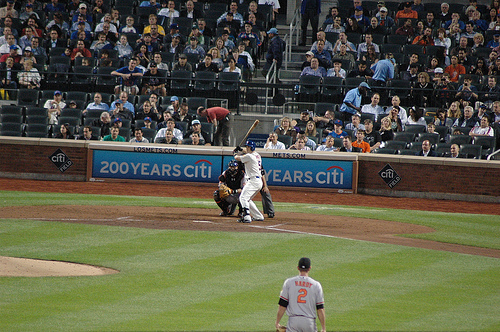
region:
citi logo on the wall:
[48, 147, 73, 169]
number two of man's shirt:
[290, 275, 317, 310]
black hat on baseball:
[297, 253, 315, 270]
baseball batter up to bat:
[240, 105, 266, 222]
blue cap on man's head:
[50, 85, 67, 97]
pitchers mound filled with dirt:
[2, 253, 129, 293]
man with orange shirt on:
[352, 127, 373, 149]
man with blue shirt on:
[342, 74, 378, 114]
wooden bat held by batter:
[217, 113, 258, 163]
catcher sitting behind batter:
[213, 153, 253, 211]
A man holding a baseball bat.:
[214, 114, 286, 231]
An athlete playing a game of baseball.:
[195, 103, 296, 247]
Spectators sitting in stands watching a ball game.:
[8, 4, 495, 142]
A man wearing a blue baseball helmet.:
[206, 118, 296, 239]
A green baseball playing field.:
[6, 185, 250, 329]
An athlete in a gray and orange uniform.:
[245, 240, 354, 329]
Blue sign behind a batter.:
[78, 140, 224, 186]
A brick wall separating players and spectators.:
[366, 157, 497, 206]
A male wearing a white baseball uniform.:
[212, 111, 286, 235]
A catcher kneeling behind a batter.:
[201, 146, 295, 240]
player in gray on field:
[259, 225, 339, 325]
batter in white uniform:
[217, 137, 268, 231]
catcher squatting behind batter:
[209, 141, 254, 227]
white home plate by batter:
[192, 212, 217, 230]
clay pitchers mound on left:
[7, 247, 120, 279]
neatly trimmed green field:
[144, 238, 373, 313]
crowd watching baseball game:
[43, 4, 499, 149]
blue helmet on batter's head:
[244, 134, 263, 156]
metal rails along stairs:
[259, 61, 291, 93]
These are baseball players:
[191, 127, 289, 326]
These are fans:
[91, 5, 312, 147]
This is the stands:
[186, 47, 261, 101]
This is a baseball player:
[221, 228, 366, 329]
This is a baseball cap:
[265, 235, 317, 276]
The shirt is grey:
[268, 260, 337, 324]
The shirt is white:
[218, 125, 275, 203]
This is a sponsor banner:
[106, 118, 260, 209]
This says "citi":
[381, 152, 416, 246]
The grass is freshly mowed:
[154, 303, 166, 315]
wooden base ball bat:
[231, 113, 262, 153]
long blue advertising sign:
[87, 140, 382, 195]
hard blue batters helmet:
[242, 136, 259, 153]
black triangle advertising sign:
[47, 145, 85, 170]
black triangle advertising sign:
[376, 158, 406, 190]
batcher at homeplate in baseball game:
[212, 157, 254, 209]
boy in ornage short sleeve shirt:
[353, 125, 370, 151]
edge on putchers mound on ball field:
[2, 239, 139, 317]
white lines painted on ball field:
[106, 196, 393, 265]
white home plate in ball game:
[186, 205, 216, 229]